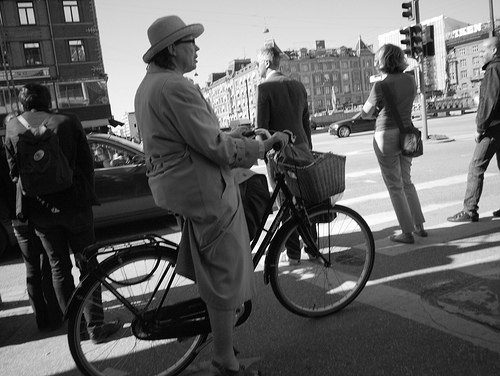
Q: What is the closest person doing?
A: Walking a bike.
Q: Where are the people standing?
A: ON the side of the road.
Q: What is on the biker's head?
A: A hat.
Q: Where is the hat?
A: On the biker's head.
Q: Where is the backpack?
A: On the left man's back.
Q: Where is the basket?
A: On the bike.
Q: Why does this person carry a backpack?
A: To hold their belongings.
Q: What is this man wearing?
A: A suit.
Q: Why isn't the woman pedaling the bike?
A: She is waiting at a stop light.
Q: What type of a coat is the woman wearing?
A: A trench coat.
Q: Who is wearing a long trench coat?
A: The woman on the bicycle.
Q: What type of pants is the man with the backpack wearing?
A: Dark jeans.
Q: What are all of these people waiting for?
A: Walk sign.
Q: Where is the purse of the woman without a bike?
A: Behind her.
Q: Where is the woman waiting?
A: On the sidewalk.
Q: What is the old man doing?
A: Riding the bike.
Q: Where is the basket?
A: In front of the bike.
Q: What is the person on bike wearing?
A: A coat.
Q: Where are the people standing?
A: At the sidewalk.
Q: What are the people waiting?
A: To cross the street.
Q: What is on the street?
A: Cars.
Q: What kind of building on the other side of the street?
A: An abbey.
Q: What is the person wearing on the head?
A: A hat.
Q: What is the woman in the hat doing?
A: Riding a bike.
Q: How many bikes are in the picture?
A: One.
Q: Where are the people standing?
A: Corner.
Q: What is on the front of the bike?
A: Basket.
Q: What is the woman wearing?
A: Dress.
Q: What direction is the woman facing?
A: Right.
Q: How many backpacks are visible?
A: One.